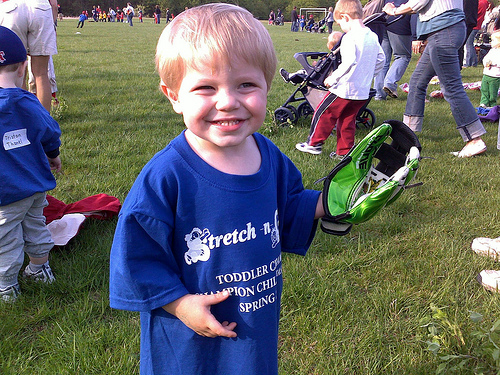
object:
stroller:
[295, 0, 387, 162]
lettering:
[215, 264, 269, 285]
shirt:
[108, 127, 324, 375]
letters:
[183, 221, 257, 265]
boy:
[107, 2, 421, 375]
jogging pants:
[306, 90, 369, 155]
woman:
[381, 0, 488, 158]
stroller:
[278, 30, 345, 87]